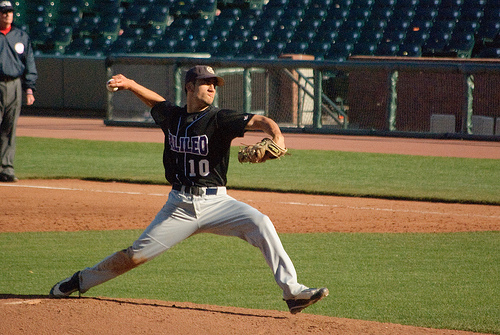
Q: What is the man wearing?
A: A uniform.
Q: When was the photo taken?
A: During the day.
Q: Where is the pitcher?
A: The mound.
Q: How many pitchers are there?
A: One.